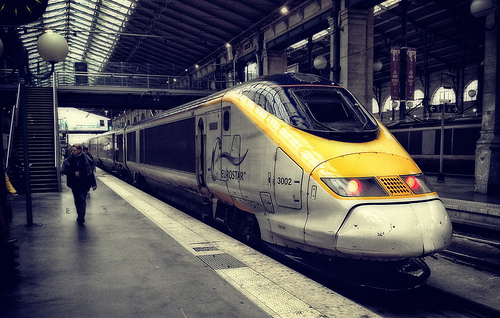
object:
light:
[38, 32, 68, 62]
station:
[1, 1, 498, 314]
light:
[302, 45, 342, 75]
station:
[16, 8, 480, 253]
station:
[15, 15, 481, 306]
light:
[364, 37, 403, 91]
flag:
[368, 33, 439, 123]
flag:
[383, 40, 449, 116]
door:
[263, 132, 328, 264]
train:
[90, 52, 444, 268]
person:
[59, 139, 158, 248]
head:
[55, 127, 105, 161]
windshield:
[237, 55, 400, 144]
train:
[80, 81, 484, 303]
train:
[90, 58, 452, 313]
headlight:
[330, 148, 456, 208]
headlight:
[393, 155, 457, 248]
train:
[70, 43, 453, 283]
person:
[57, 129, 116, 254]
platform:
[10, 171, 198, 314]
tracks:
[454, 218, 484, 286]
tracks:
[447, 213, 481, 293]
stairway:
[12, 75, 97, 216]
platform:
[109, 229, 211, 297]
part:
[54, 246, 195, 300]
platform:
[14, 250, 92, 310]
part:
[29, 245, 139, 289]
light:
[34, 28, 101, 103]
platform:
[49, 204, 99, 263]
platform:
[420, 155, 481, 197]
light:
[267, 4, 307, 24]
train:
[114, 45, 482, 278]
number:
[249, 149, 306, 206]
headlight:
[310, 178, 381, 210]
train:
[120, 65, 466, 283]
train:
[114, 60, 455, 275]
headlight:
[395, 157, 475, 206]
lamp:
[34, 24, 94, 74]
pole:
[23, 55, 68, 89]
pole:
[25, 61, 75, 97]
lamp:
[34, 16, 82, 69]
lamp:
[302, 50, 349, 86]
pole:
[319, 32, 354, 80]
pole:
[368, 75, 386, 101]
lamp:
[365, 45, 385, 83]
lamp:
[460, 84, 479, 105]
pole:
[471, 97, 484, 129]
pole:
[404, 93, 421, 126]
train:
[92, 90, 498, 256]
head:
[73, 127, 96, 167]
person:
[48, 115, 118, 251]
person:
[53, 129, 107, 241]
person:
[69, 130, 112, 244]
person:
[73, 129, 105, 235]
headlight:
[337, 175, 358, 207]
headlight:
[399, 170, 421, 197]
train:
[50, 77, 434, 290]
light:
[29, 31, 69, 71]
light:
[293, 52, 335, 80]